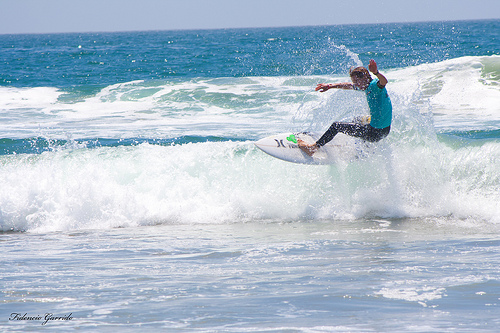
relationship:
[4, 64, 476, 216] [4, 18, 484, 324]
waves in ocean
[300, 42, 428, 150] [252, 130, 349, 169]
spray by board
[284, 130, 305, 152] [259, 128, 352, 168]
sticker on board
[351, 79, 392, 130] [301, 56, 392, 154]
rashguard of boarder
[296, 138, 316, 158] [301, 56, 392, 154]
foot of boarder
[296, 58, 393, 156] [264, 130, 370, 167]
boarder riding board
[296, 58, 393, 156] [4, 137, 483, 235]
boarder on wave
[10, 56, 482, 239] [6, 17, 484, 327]
waves on water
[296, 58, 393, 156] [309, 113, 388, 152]
boarder wearing pants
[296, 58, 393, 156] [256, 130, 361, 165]
boarder on surfboard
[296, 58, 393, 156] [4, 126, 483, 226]
boarder on wave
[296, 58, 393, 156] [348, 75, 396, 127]
boarder in shirt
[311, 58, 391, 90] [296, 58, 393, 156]
arms of boarder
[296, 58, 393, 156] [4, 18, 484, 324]
boarder in ocean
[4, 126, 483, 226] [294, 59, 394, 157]
wave under surfer